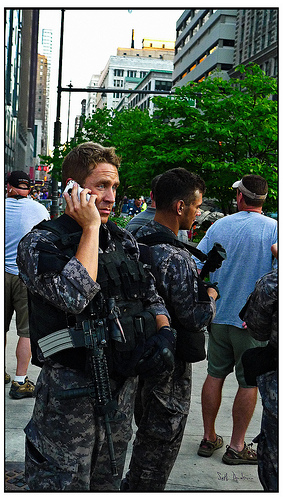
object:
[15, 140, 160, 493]
man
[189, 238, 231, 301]
guns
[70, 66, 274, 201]
leaves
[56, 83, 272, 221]
trees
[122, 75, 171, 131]
building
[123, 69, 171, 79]
roof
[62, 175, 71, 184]
ear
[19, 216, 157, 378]
vest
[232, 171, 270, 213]
head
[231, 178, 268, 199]
visor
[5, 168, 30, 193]
baseball hat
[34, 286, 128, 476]
gun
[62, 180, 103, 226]
right hand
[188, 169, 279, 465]
man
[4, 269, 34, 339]
shorts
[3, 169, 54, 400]
man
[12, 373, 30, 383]
sock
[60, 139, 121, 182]
hair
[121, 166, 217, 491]
soldier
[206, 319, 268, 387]
shorts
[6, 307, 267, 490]
street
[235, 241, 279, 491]
soldier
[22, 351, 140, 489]
pants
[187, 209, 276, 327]
shirt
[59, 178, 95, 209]
cell phone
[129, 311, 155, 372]
gun